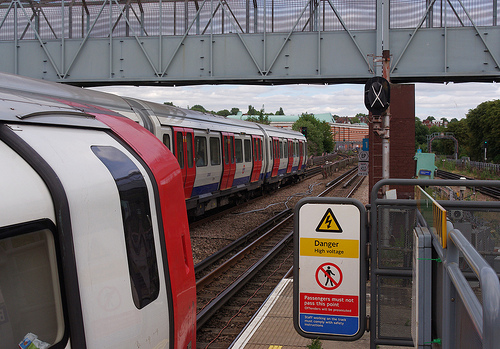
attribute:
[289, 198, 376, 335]
emblem — yellow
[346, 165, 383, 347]
pole — black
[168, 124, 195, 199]
door — red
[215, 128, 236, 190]
door — red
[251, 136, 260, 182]
door — red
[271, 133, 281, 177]
door — red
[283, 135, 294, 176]
door — red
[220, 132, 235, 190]
doors — red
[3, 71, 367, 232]
train — white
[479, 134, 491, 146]
light — green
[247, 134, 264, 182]
door — red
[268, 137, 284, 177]
door — red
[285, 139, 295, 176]
door — red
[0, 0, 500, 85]
bridge — grey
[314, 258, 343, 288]
emblem — red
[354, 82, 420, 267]
pole — silver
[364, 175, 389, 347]
pole — black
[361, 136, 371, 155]
sign — blue